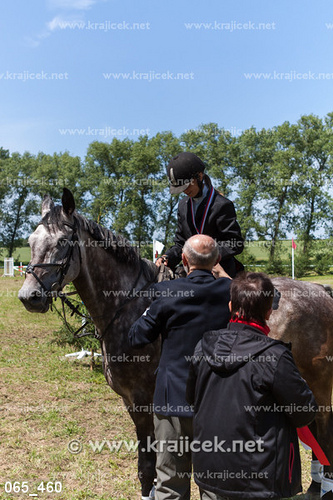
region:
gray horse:
[21, 188, 98, 322]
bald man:
[167, 225, 212, 277]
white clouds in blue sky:
[13, 15, 60, 72]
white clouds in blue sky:
[81, 65, 123, 90]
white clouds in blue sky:
[193, 63, 225, 101]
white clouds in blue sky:
[202, 48, 234, 81]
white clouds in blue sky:
[79, 78, 108, 104]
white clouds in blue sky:
[231, 21, 283, 54]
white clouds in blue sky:
[136, 7, 166, 48]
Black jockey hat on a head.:
[163, 151, 206, 194]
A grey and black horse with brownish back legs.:
[16, 194, 331, 498]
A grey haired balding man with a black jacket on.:
[128, 235, 236, 498]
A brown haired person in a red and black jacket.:
[190, 269, 317, 498]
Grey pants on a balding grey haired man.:
[151, 410, 193, 498]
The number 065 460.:
[3, 481, 62, 494]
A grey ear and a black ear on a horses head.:
[40, 187, 75, 213]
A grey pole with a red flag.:
[290, 237, 296, 276]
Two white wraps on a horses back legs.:
[308, 456, 331, 494]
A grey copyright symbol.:
[68, 436, 81, 454]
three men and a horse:
[11, 149, 330, 498]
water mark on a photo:
[92, 399, 203, 418]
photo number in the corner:
[1, 465, 68, 494]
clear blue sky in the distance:
[21, 59, 276, 116]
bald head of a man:
[175, 229, 223, 272]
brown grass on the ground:
[8, 385, 125, 491]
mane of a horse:
[83, 209, 150, 270]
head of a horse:
[14, 182, 77, 318]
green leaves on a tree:
[224, 110, 328, 206]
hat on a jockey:
[166, 146, 214, 194]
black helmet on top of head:
[159, 154, 232, 206]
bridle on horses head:
[22, 260, 59, 287]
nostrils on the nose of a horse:
[16, 282, 46, 307]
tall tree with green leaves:
[245, 132, 277, 159]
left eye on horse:
[54, 231, 75, 259]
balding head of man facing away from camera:
[183, 231, 221, 270]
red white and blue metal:
[177, 192, 220, 235]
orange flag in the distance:
[288, 240, 308, 259]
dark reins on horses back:
[104, 264, 150, 327]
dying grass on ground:
[13, 407, 66, 456]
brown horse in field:
[18, 182, 332, 496]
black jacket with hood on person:
[187, 325, 316, 498]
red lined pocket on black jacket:
[284, 439, 296, 485]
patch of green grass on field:
[2, 326, 46, 496]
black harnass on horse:
[23, 221, 80, 309]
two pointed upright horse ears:
[37, 187, 79, 220]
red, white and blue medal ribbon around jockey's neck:
[181, 183, 219, 234]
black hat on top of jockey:
[157, 148, 209, 200]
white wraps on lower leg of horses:
[304, 453, 331, 498]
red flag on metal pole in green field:
[286, 235, 304, 278]